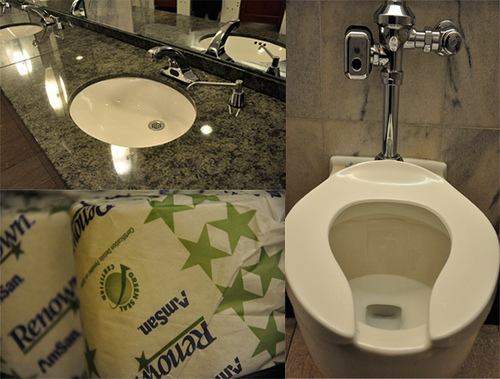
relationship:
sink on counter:
[1, 0, 58, 42] [1, 0, 283, 188]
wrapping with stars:
[3, 190, 285, 370] [140, 187, 281, 358]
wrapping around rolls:
[3, 190, 285, 370] [0, 195, 285, 372]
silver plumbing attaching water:
[346, 0, 463, 162] [367, 300, 403, 330]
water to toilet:
[367, 300, 403, 330] [286, 151, 497, 376]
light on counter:
[199, 122, 211, 132] [1, 0, 283, 188]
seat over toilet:
[289, 153, 487, 374] [286, 151, 497, 376]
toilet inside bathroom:
[286, 151, 497, 376] [290, 5, 498, 377]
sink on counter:
[66, 70, 199, 150] [0, 31, 286, 189]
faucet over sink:
[143, 43, 200, 91] [66, 70, 199, 150]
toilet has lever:
[286, 151, 497, 376] [436, 20, 462, 60]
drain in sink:
[144, 113, 165, 133] [64, 70, 200, 162]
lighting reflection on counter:
[3, 32, 217, 182] [1, 0, 283, 188]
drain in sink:
[144, 113, 165, 133] [66, 70, 199, 150]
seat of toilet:
[308, 283, 339, 314] [278, 157, 481, 356]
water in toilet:
[367, 300, 403, 330] [277, 131, 499, 376]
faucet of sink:
[143, 43, 200, 91] [65, 65, 197, 157]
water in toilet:
[367, 300, 403, 330] [299, 77, 483, 376]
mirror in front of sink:
[0, 1, 285, 80] [0, 1, 285, 189]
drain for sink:
[144, 113, 165, 133] [55, 69, 198, 148]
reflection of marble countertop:
[10, 16, 66, 81] [6, 19, 283, 187]